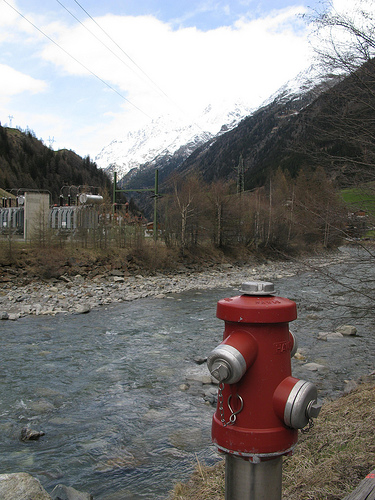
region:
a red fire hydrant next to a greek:
[181, 279, 337, 464]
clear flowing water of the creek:
[56, 339, 186, 478]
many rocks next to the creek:
[13, 272, 200, 311]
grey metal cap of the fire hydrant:
[208, 345, 253, 386]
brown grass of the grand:
[303, 413, 360, 496]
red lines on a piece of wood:
[354, 467, 373, 482]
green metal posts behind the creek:
[107, 171, 165, 241]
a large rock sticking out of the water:
[314, 319, 358, 346]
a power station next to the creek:
[14, 179, 155, 239]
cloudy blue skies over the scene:
[136, 0, 255, 92]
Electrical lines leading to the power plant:
[0, 0, 199, 128]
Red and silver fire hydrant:
[206, 278, 323, 499]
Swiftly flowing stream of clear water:
[1, 243, 373, 496]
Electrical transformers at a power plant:
[1, 158, 260, 249]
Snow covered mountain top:
[91, 53, 366, 182]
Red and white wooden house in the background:
[339, 205, 369, 224]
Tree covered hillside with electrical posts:
[1, 120, 148, 220]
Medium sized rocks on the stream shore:
[0, 256, 328, 320]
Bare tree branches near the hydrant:
[271, 13, 373, 329]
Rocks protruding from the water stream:
[3, 304, 358, 497]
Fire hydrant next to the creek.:
[204, 261, 321, 485]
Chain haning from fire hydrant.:
[195, 372, 238, 422]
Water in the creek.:
[43, 324, 168, 439]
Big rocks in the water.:
[324, 306, 374, 360]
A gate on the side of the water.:
[44, 206, 300, 251]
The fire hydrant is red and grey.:
[203, 292, 319, 455]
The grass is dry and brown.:
[316, 412, 364, 481]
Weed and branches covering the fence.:
[238, 166, 349, 234]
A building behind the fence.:
[35, 182, 100, 230]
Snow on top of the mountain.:
[102, 107, 272, 148]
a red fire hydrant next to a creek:
[194, 289, 308, 472]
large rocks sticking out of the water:
[310, 323, 359, 349]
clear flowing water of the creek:
[67, 369, 175, 452]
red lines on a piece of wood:
[362, 462, 373, 484]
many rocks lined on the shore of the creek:
[11, 265, 217, 319]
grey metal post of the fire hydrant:
[212, 454, 290, 498]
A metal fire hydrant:
[207, 281, 318, 499]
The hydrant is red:
[212, 292, 297, 451]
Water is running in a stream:
[2, 315, 201, 473]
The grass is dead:
[311, 402, 373, 471]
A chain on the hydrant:
[216, 376, 236, 426]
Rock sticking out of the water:
[20, 424, 45, 441]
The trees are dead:
[177, 202, 332, 244]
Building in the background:
[50, 206, 98, 234]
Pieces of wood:
[342, 465, 373, 497]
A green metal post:
[152, 203, 156, 242]